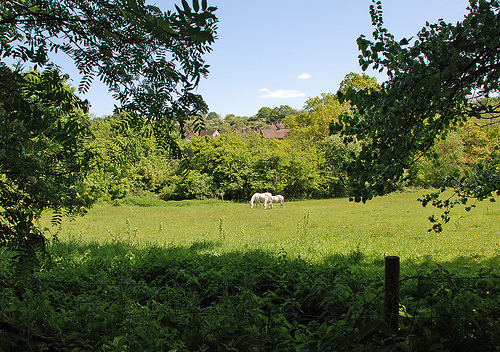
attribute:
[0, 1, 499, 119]
sky — blue, clear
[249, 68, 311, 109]
clouds — white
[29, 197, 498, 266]
grass — green, lush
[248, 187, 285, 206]
horses — eating, white, grazing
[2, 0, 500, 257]
trees — tall, green, leafy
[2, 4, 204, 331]
tree — green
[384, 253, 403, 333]
fencepost — wooden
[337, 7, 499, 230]
branches — leafy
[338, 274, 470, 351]
wire — broken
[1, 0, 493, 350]
scene — pasture view, daytime, outdoors